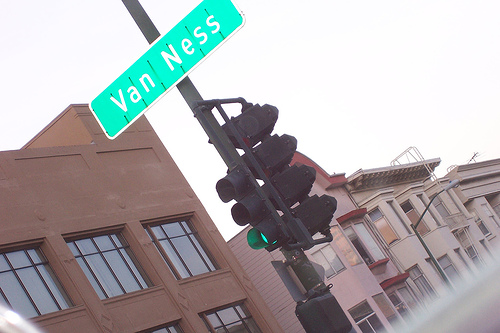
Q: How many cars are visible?
A: 0.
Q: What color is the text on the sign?
A: White.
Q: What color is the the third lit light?
A: Green.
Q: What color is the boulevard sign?
A: Green and white.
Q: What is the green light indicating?
A: Go.